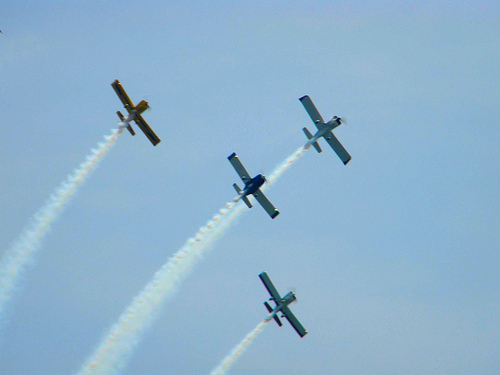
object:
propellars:
[333, 115, 346, 123]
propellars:
[260, 173, 268, 182]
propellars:
[141, 97, 153, 111]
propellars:
[290, 291, 296, 300]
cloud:
[0, 128, 124, 317]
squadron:
[110, 79, 352, 338]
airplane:
[110, 79, 161, 146]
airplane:
[298, 94, 352, 164]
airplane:
[227, 152, 280, 220]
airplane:
[258, 271, 308, 338]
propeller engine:
[334, 115, 344, 123]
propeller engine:
[259, 173, 268, 182]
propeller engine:
[141, 99, 151, 109]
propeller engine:
[290, 291, 297, 300]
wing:
[299, 94, 326, 129]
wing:
[325, 131, 352, 166]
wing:
[280, 306, 307, 338]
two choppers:
[227, 94, 352, 219]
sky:
[0, 0, 500, 375]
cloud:
[74, 145, 310, 375]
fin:
[302, 127, 323, 154]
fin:
[263, 301, 282, 326]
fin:
[232, 183, 253, 209]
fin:
[116, 110, 137, 136]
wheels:
[327, 138, 330, 140]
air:
[0, 0, 500, 375]